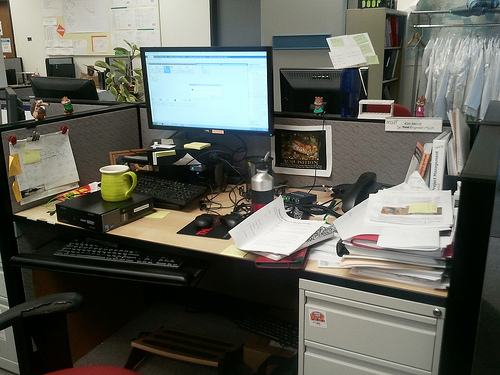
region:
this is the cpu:
[57, 196, 107, 234]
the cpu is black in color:
[70, 190, 85, 205]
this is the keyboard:
[140, 176, 190, 217]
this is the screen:
[145, 52, 266, 124]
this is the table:
[115, 225, 175, 255]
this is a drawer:
[305, 291, 410, 361]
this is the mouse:
[190, 205, 215, 230]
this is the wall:
[160, 5, 200, 22]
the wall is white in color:
[165, 2, 190, 23]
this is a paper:
[250, 205, 298, 250]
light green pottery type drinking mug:
[91, 161, 140, 208]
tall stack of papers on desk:
[327, 171, 468, 273]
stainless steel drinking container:
[245, 156, 279, 230]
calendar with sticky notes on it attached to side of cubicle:
[4, 125, 89, 206]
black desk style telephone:
[327, 168, 392, 210]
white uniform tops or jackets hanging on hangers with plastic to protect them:
[412, 23, 497, 113]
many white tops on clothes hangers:
[405, 26, 497, 116]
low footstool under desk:
[101, 322, 273, 373]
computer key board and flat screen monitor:
[134, 36, 277, 206]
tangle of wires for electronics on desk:
[200, 138, 251, 213]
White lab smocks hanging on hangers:
[414, 22, 499, 122]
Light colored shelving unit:
[343, 7, 410, 109]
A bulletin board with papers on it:
[38, 0, 163, 58]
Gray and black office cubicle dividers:
[0, 96, 499, 374]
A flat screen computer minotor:
[138, 44, 275, 138]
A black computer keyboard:
[50, 237, 186, 269]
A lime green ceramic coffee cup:
[96, 161, 136, 201]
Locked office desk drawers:
[296, 275, 446, 374]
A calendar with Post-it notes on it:
[6, 123, 81, 207]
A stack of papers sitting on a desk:
[330, 180, 453, 291]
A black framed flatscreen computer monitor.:
[133, 47, 275, 136]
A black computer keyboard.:
[57, 241, 184, 269]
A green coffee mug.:
[98, 163, 140, 201]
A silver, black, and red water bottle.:
[253, 160, 273, 212]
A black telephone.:
[332, 172, 390, 211]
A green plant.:
[94, 40, 146, 102]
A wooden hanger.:
[408, 26, 421, 48]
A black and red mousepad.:
[172, 212, 241, 242]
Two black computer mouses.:
[194, 209, 241, 230]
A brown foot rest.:
[118, 325, 247, 373]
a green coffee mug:
[99, 159, 138, 203]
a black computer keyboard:
[54, 235, 194, 278]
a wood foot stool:
[118, 320, 250, 368]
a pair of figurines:
[27, 93, 77, 120]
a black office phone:
[338, 168, 400, 213]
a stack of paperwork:
[321, 173, 456, 290]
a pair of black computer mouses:
[194, 209, 246, 236]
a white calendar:
[1, 130, 85, 197]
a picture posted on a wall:
[265, 123, 336, 180]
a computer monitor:
[137, 35, 282, 139]